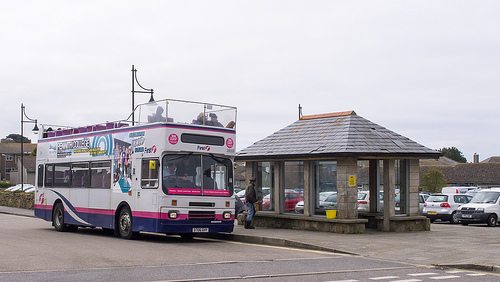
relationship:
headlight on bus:
[167, 209, 182, 222] [34, 96, 235, 243]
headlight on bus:
[221, 210, 233, 222] [34, 96, 235, 243]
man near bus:
[242, 178, 260, 231] [34, 96, 235, 243]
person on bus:
[209, 112, 222, 128] [34, 96, 235, 243]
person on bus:
[149, 103, 172, 123] [34, 96, 235, 243]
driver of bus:
[163, 163, 182, 181] [34, 96, 235, 243]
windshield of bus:
[163, 152, 235, 198] [34, 96, 235, 243]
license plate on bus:
[191, 225, 213, 234] [34, 96, 235, 243]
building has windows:
[2, 143, 35, 183] [6, 154, 15, 163]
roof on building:
[2, 141, 37, 154] [2, 143, 35, 183]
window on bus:
[165, 98, 238, 132] [34, 96, 235, 243]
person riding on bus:
[209, 112, 222, 128] [34, 96, 235, 243]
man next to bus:
[242, 178, 260, 231] [34, 96, 235, 243]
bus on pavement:
[34, 96, 235, 243] [300, 257, 377, 278]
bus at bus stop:
[34, 96, 235, 243] [236, 105, 437, 234]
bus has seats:
[34, 96, 235, 243] [105, 122, 129, 131]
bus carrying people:
[34, 96, 235, 243] [192, 114, 223, 126]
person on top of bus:
[209, 112, 222, 128] [34, 96, 235, 243]